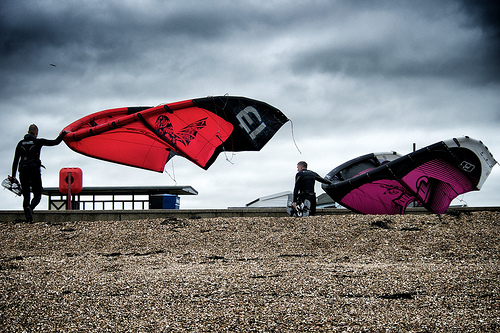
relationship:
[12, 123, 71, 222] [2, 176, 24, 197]
man holds packet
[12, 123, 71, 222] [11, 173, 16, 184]
man has hand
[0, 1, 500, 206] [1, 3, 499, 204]
skies has clouds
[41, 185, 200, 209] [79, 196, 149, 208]
bench has partition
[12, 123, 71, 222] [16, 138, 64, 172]
man wearing shirt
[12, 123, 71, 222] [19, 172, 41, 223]
man wearing pants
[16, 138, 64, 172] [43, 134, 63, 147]
shirt has sleeve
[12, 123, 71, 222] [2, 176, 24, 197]
man carries equipment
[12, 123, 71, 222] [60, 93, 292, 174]
person holds something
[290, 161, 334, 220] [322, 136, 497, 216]
person holds something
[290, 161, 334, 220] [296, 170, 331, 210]
person wears outfit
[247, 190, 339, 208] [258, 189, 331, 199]
building has roof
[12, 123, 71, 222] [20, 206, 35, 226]
person wears shoes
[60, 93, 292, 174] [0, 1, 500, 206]
object flies in the air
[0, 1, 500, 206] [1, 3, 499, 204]
sky has clouds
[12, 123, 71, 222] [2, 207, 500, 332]
person stands on ground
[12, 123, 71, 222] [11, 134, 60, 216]
man wears uniform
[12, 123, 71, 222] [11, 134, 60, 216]
man wears suit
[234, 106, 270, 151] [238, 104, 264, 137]
design has letters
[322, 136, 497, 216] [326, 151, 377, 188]
wings has trim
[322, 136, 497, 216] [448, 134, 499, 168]
wings have tips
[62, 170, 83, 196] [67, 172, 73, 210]
square attaches post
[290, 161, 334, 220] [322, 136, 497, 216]
man holds wings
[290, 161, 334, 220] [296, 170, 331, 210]
man wears suit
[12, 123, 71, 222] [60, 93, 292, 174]
man holds wings